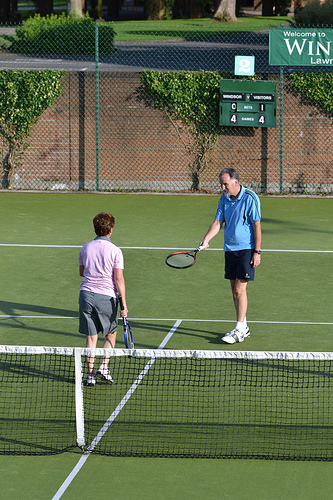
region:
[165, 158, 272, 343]
This man is wearing a light blue polo shirt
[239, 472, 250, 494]
The color of this tennis court is clearly green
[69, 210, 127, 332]
This woman is wearing a light pink polo shirt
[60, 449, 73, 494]
There is a white line on the tennis court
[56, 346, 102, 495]
There is a white divider in the middle of the net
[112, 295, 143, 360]
The woman has a blue racket in her hand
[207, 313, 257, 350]
The man has black and white tennis shoes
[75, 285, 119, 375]
The woman has gray shorts for tennis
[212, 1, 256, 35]
There is a very, very large tree in the background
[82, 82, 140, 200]
The brick wall serves as a barrier for the tennis court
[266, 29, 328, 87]
a welcome sign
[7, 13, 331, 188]
a fence around a tennis court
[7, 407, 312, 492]
a green tennis court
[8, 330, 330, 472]
a white tennis net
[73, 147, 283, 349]
two people playing tennis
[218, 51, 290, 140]
a scoreboard on the tennis court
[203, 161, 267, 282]
a man wearing a blue shirt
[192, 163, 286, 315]
a man wearing blue shorts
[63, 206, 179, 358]
a woman wearing a pink shirt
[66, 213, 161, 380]
a woman wearing grey shorts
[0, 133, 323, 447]
Picture of two people playing tennis.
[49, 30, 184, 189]
A fence along the back of the court.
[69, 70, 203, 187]
A brick wall in the background.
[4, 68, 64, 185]
Green tree growing in front of brick wall.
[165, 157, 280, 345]
Person on right holding a tennis raquet.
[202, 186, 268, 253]
Light blue short sleeve shirt.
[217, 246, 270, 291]
A pair of dark shorts.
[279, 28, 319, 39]
The word Welcome in white letters.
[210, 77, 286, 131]
A green scoreboard.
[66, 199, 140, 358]
Person with tennis raquet in right hand.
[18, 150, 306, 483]
A scene on a tennis court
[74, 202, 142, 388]
A woman holding a tennis racket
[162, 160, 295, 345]
A man holding a tennis racket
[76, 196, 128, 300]
A woman in a pink shirt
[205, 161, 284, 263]
A man in a blue shirt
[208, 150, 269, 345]
A man wearing tennis shoes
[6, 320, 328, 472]
A net across a tennis court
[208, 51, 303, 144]
A score board on a fence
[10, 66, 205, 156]
Shrubbery growing on a fence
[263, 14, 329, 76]
A sign on a fence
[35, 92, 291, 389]
Two people playing tennis.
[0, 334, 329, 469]
A net.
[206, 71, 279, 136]
A scoreboard is attached to the fence.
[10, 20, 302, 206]
A large chain-link fence.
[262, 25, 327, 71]
A green banner.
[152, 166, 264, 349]
The man is wearing a blue shirt.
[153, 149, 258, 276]
The man is holding a tennis racket in his right hand.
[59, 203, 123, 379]
The woman is wearing a pink shirt and gray shorts.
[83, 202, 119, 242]
The woman has short hair.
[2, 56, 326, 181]
Bushes are behind the fence.